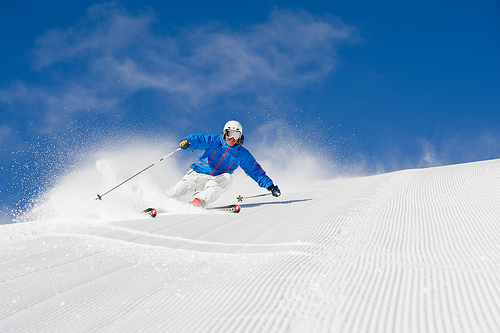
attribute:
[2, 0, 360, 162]
clouds — white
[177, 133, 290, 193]
parka — blue 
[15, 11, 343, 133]
clouds — white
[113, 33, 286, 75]
clouds — white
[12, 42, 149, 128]
sky — blue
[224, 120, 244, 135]
helmet — white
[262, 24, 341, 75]
clouds — white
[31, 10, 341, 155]
clouds — white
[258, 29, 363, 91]
sky — blue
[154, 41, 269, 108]
clouds — white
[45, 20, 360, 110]
clouds — white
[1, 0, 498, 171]
sky — blue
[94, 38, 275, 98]
clouds — white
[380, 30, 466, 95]
sky — blue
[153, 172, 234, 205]
pants — white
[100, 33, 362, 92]
clouds — white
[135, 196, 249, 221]
skis — red , black 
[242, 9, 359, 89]
cloud — white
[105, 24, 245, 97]
cloud — white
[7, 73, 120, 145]
cloud — white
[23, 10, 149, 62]
cloud — white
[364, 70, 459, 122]
sky — blue 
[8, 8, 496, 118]
sky — blue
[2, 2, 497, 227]
sky — blue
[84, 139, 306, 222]
pants — white 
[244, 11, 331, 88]
clouds — white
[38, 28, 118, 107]
clouds — white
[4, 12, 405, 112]
clouds — white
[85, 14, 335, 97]
clouds — white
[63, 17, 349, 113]
clouds — white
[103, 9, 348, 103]
clouds — white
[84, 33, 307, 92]
clouds — white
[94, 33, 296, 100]
clouds — white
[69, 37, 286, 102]
clouds — white